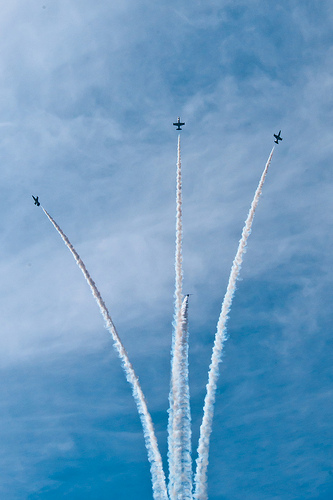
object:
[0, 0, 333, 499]
sky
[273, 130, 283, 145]
jet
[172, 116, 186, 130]
jet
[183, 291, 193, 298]
jet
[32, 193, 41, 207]
jet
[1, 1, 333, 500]
cloudy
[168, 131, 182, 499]
thick contrails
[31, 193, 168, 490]
left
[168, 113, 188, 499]
upwards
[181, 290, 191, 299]
bottom jet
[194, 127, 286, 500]
right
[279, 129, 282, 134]
nose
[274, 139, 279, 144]
tail